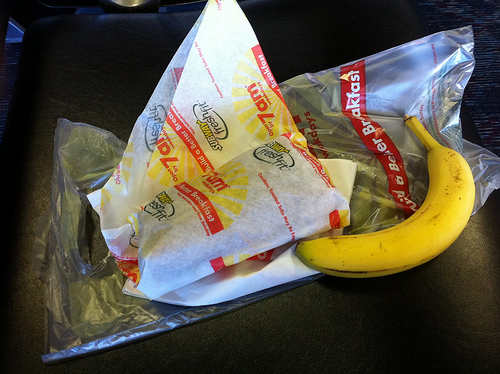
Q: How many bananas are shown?
A: One.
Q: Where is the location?
A: Dining room.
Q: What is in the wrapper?
A: A sandwich.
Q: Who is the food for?
A: A man.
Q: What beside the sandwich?
A: Banana.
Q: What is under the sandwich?
A: Plastic bag.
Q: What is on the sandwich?
A: A wrapper.